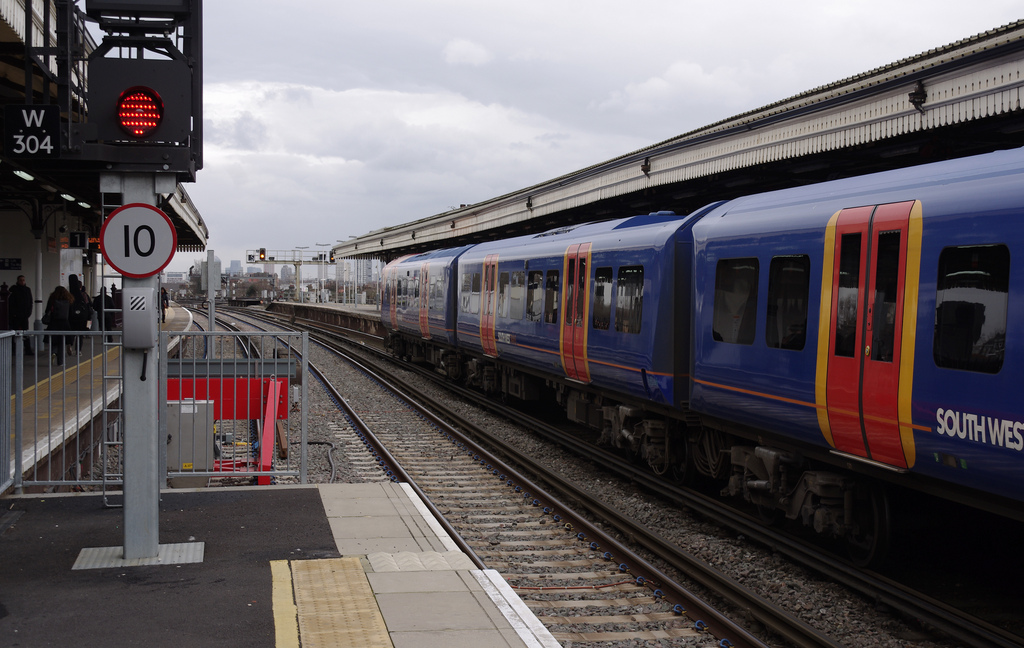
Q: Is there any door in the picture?
A: Yes, there are doors.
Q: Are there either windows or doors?
A: Yes, there are doors.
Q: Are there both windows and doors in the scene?
A: Yes, there are both doors and a window.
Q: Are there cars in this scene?
A: No, there are no cars.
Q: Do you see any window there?
A: Yes, there is a window.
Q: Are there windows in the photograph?
A: Yes, there is a window.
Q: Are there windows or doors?
A: Yes, there is a window.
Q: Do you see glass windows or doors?
A: Yes, there is a glass window.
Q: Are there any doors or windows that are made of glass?
A: Yes, the window is made of glass.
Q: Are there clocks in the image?
A: No, there are no clocks.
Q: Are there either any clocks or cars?
A: No, there are no clocks or cars.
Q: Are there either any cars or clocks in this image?
A: No, there are no clocks or cars.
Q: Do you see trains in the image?
A: Yes, there is a train.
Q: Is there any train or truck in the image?
A: Yes, there is a train.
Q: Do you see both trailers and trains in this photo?
A: No, there is a train but no trailers.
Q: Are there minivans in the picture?
A: No, there are no minivans.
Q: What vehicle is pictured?
A: The vehicle is a train.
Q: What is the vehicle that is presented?
A: The vehicle is a train.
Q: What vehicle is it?
A: The vehicle is a train.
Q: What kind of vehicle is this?
A: This is a train.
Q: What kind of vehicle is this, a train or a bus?
A: This is a train.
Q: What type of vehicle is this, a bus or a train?
A: This is a train.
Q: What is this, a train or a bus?
A: This is a train.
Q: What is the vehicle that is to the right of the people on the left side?
A: The vehicle is a train.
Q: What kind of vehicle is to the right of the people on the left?
A: The vehicle is a train.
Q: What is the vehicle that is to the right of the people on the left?
A: The vehicle is a train.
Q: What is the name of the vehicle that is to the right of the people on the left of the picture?
A: The vehicle is a train.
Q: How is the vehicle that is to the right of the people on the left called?
A: The vehicle is a train.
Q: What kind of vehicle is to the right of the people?
A: The vehicle is a train.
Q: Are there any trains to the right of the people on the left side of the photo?
A: Yes, there is a train to the right of the people.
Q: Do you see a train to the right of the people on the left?
A: Yes, there is a train to the right of the people.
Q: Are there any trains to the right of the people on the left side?
A: Yes, there is a train to the right of the people.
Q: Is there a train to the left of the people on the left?
A: No, the train is to the right of the people.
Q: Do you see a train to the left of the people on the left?
A: No, the train is to the right of the people.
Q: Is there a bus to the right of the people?
A: No, there is a train to the right of the people.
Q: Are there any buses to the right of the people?
A: No, there is a train to the right of the people.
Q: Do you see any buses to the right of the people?
A: No, there is a train to the right of the people.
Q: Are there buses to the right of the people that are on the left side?
A: No, there is a train to the right of the people.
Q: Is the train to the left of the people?
A: No, the train is to the right of the people.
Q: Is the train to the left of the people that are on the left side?
A: No, the train is to the right of the people.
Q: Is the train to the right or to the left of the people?
A: The train is to the right of the people.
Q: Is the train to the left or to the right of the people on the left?
A: The train is to the right of the people.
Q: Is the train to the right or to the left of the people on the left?
A: The train is to the right of the people.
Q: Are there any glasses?
A: No, there are no glasses.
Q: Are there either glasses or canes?
A: No, there are no glasses or canes.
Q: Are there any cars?
A: No, there are no cars.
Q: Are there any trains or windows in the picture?
A: Yes, there is a window.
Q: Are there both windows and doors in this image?
A: Yes, there are both a window and a door.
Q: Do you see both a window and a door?
A: Yes, there are both a window and a door.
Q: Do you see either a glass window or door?
A: Yes, there is a glass window.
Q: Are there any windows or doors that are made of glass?
A: Yes, the window is made of glass.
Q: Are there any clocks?
A: No, there are no clocks.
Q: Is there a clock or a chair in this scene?
A: No, there are no clocks or chairs.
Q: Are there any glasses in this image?
A: No, there are no glasses.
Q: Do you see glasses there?
A: No, there are no glasses.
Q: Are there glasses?
A: No, there are no glasses.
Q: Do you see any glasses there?
A: No, there are no glasses.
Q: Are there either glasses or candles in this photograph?
A: No, there are no glasses or candles.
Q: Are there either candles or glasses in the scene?
A: No, there are no glasses or candles.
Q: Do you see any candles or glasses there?
A: No, there are no glasses or candles.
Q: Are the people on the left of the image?
A: Yes, the people are on the left of the image.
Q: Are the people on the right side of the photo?
A: No, the people are on the left of the image.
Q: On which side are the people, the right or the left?
A: The people are on the left of the image.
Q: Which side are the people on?
A: The people are on the left of the image.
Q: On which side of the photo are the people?
A: The people are on the left of the image.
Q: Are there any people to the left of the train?
A: Yes, there are people to the left of the train.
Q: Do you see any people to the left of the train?
A: Yes, there are people to the left of the train.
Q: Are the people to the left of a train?
A: Yes, the people are to the left of a train.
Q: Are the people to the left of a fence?
A: No, the people are to the left of a train.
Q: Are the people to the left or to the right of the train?
A: The people are to the left of the train.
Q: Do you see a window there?
A: Yes, there is a window.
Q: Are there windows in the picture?
A: Yes, there is a window.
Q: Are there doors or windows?
A: Yes, there is a window.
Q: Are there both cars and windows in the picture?
A: No, there is a window but no cars.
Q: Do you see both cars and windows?
A: No, there is a window but no cars.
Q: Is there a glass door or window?
A: Yes, there is a glass window.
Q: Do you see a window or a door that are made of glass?
A: Yes, the window is made of glass.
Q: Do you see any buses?
A: No, there are no buses.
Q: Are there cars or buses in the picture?
A: No, there are no buses or cars.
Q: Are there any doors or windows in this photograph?
A: Yes, there is a window.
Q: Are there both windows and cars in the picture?
A: No, there is a window but no cars.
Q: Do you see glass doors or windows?
A: Yes, there is a glass window.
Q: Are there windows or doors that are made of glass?
A: Yes, the window is made of glass.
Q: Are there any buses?
A: No, there are no buses.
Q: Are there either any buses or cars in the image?
A: No, there are no buses or cars.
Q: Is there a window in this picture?
A: Yes, there is a window.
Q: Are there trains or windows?
A: Yes, there is a window.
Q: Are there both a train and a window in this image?
A: Yes, there are both a window and a train.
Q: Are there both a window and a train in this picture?
A: Yes, there are both a window and a train.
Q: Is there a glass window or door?
A: Yes, there is a glass window.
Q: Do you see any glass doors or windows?
A: Yes, there is a glass window.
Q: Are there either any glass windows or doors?
A: Yes, there is a glass window.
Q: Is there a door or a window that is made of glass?
A: Yes, the window is made of glass.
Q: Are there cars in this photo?
A: No, there are no cars.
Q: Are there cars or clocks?
A: No, there are no cars or clocks.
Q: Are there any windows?
A: Yes, there is a window.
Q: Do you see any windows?
A: Yes, there is a window.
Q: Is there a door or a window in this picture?
A: Yes, there is a window.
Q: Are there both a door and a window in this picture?
A: Yes, there are both a window and a door.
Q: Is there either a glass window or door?
A: Yes, there is a glass window.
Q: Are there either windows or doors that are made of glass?
A: Yes, the window is made of glass.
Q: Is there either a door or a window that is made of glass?
A: Yes, the window is made of glass.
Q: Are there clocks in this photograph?
A: No, there are no clocks.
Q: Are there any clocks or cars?
A: No, there are no clocks or cars.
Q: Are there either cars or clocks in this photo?
A: No, there are no clocks or cars.